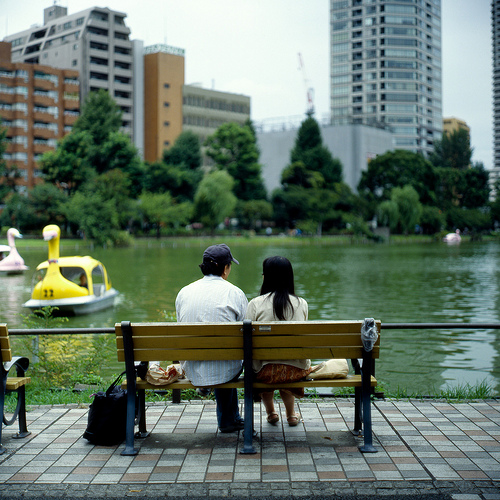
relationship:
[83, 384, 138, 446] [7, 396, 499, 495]
bag on ground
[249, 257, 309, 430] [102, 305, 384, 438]
lady sitting on bench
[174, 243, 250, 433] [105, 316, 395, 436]
man sitting on bench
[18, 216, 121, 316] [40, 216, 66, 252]
boat with duck head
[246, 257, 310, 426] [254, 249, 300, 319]
lady with hair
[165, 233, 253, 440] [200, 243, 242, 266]
man wearing hat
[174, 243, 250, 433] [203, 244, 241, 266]
man wearing cap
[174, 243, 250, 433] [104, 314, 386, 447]
man sitting on bench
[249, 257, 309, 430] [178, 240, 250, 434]
lady sitting next to man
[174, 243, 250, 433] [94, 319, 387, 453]
man sitting on bench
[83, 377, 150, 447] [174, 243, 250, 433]
bag next to man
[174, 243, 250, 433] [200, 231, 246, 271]
man wearing cap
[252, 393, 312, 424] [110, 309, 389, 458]
legs of benches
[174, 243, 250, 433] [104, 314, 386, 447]
man on bench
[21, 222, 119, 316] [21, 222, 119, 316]
boat shaped boat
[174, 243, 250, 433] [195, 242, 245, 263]
man wearing cap